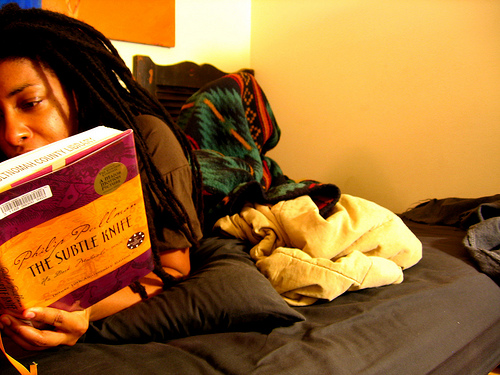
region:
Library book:
[11, 125, 156, 315]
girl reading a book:
[0, 5, 195, 346]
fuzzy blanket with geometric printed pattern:
[171, 57, 336, 219]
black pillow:
[90, 235, 301, 345]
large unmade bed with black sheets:
[85, 190, 490, 365]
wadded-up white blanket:
[213, 191, 423, 306]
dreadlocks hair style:
[80, 28, 205, 248]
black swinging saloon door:
[127, 50, 248, 125]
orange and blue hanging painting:
[0, 0, 175, 47]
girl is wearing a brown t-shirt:
[128, 113, 206, 260]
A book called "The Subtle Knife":
[8, 146, 165, 333]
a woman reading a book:
[7, 10, 212, 354]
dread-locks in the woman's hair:
[39, 19, 141, 141]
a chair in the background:
[137, 51, 273, 136]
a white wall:
[255, 11, 497, 188]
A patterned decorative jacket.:
[182, 83, 341, 213]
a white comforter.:
[260, 213, 406, 290]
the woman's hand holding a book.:
[14, 303, 116, 364]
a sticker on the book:
[89, 167, 136, 199]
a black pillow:
[141, 236, 318, 353]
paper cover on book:
[1, 126, 153, 312]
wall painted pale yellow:
[250, 0, 497, 211]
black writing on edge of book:
[0, 135, 100, 180]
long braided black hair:
[0, 1, 205, 249]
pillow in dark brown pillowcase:
[82, 235, 305, 345]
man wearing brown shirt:
[127, 111, 202, 251]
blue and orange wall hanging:
[0, 0, 175, 50]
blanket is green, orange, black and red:
[173, 66, 340, 227]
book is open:
[0, 123, 155, 321]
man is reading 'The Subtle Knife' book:
[1, 1, 203, 353]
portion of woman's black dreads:
[62, 7, 135, 115]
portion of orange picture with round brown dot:
[90, 2, 204, 44]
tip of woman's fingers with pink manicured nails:
[18, 307, 51, 323]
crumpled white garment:
[231, 198, 420, 295]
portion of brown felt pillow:
[223, 257, 300, 331]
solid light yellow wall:
[276, 12, 488, 157]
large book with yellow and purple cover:
[3, 122, 165, 309]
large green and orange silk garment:
[161, 55, 291, 187]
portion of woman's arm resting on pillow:
[155, 244, 200, 294]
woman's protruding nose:
[5, 122, 35, 152]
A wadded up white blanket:
[216, 182, 422, 296]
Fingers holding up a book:
[1, 304, 93, 356]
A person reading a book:
[0, 5, 210, 354]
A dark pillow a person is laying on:
[87, 235, 312, 347]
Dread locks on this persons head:
[36, 3, 199, 233]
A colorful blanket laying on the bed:
[181, 71, 346, 217]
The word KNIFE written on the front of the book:
[98, 212, 134, 244]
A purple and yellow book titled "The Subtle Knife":
[0, 121, 158, 327]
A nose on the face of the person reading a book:
[1, 95, 43, 143]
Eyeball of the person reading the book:
[11, 88, 52, 113]